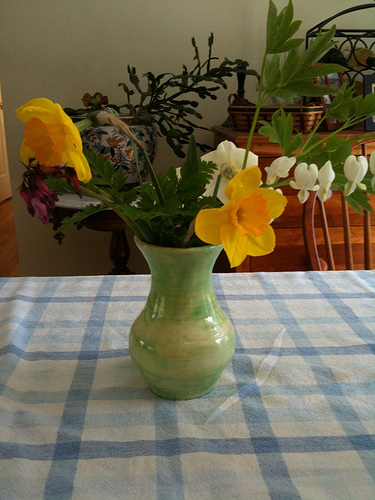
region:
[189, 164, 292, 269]
Yellow flower in vase.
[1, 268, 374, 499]
Blue and white plaid table cloth.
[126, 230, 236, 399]
Green and white vase on table.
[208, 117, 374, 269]
Wood dresser in the background.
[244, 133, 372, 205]
White bleeding heart flowers.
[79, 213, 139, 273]
Dark wooden table in background.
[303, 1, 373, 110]
Wrought iron wine rack in the background.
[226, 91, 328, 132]
Wicker basket on dresser.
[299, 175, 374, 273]
Wooden chair behind table.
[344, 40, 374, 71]
Wine bottle in rack.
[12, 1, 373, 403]
A green vase of flowers on a table.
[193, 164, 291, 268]
A pretty yellow flower in a vase.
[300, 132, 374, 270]
A chair sitting behind a table.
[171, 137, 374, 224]
White flowers in a vase.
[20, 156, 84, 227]
A wilted purple flower in a vase.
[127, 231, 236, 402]
A green flower vase.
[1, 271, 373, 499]
A blue and white tablecloth on a table.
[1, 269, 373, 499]
A table with a vase of flowers sitting on it.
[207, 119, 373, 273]
A wooden cabinet sitting behind a table.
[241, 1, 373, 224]
Green leafy plants in a flower vase.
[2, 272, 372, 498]
Blue and white table cloth.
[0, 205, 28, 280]
Wooden furniture on the side of the wall.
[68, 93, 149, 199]
Multicolored vase on table.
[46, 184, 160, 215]
White table top in the back.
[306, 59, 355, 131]
Wooden photo frame on cabinet,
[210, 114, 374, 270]
Wooden cabinet in the background.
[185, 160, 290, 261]
Yellow flower in the vase.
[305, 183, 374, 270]
Wooden rungs in the chair.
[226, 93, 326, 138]
Rectangular basket on cabinet.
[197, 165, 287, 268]
the flower is orange in color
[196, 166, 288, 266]
the flower is on a vase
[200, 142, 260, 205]
the flower is on a vase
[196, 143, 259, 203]
the flower is white in color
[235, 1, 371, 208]
the branches are in the vase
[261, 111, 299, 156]
the leaf is green in color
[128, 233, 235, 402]
the vase is holding flowers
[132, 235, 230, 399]
the vase is textured green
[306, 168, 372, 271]
a chair is behind the table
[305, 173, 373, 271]
the chair is made of wood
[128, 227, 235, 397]
a light green ceramic vase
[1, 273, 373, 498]
a blue and white checkered tablecloth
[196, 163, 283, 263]
a yellow daffodil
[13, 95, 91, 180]
a yellow daffodil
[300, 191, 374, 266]
a brown wood chair back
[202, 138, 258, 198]
a small white flower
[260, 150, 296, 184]
a small white flower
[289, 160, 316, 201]
a small white flower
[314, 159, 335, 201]
a small white flower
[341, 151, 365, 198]
a small white flower